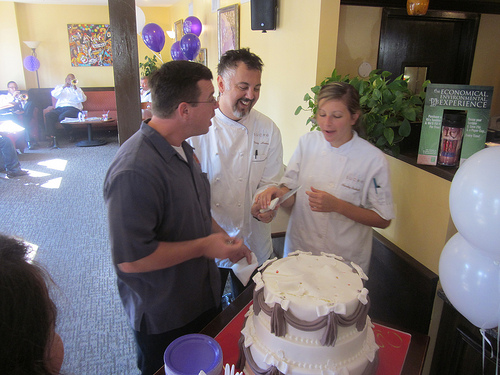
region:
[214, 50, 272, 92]
brown and white hair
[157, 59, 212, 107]
man has brown hair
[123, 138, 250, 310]
man has blue shirt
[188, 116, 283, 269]
man has white smock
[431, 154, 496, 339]
white balloons near cake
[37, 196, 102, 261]
blue and grey carpet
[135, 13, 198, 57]
purple balloons behind man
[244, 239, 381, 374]
grey and white cake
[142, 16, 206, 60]
purple ballons in the air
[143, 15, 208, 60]
four purple balloons in the air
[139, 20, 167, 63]
purple balloon on the air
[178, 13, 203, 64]
two purple balloons in the air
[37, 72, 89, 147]
person in a white shirt sitting down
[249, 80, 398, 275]
female chef with a knife in her hand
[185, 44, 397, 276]
male and female chef dressed in white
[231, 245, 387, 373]
very large multi-tier brown and white cake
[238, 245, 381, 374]
brown and white cake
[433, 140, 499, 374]
two white balloons in the air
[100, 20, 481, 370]
Some people are standing by a cake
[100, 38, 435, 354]
Some people are talking together nicely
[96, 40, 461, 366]
Some people are inside a room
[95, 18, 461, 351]
Some people are in a nice bakery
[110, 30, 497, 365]
Some people are doing their work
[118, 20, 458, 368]
Some people are tasting a nice cake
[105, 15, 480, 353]
A person is wearing nice eyeglasses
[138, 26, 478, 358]
Some people are wearing white uniforms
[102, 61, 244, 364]
this is a person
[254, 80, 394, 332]
this is a person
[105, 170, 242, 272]
this is a person's hand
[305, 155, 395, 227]
this is a person's hand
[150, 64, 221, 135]
this is a person's head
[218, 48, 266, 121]
this is a person's head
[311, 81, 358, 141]
this is a person's head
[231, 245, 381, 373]
this is a white cake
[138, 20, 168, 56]
this is a purple ballon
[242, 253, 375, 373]
a large decorative cake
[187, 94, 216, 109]
part of a man's eyeglasses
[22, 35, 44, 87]
part of a floor lamp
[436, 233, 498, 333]
a white balloon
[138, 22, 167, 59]
a purple balloon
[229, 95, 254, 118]
a man's gray and black beard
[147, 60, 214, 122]
a man's short cut hair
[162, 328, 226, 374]
a stack of purple plastic plates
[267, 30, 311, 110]
a yellow painted wall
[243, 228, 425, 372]
A white brown wedding cake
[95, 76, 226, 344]
A man in a brown shirt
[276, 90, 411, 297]
a woman in white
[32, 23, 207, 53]
Purple balloons in the background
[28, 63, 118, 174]
A man setting on the couch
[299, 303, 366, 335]
White bows on a cake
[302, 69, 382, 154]
a woman wit brown hair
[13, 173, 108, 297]
floor with dfert colors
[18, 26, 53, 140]
a tall light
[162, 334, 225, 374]
the paper plates are purple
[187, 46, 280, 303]
the man is holding a knife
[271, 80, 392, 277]
the woman is holding a kinfe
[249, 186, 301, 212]
the knife is white and silver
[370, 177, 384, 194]
the pen on the woman's shirt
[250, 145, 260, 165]
the pen in the man's pocket